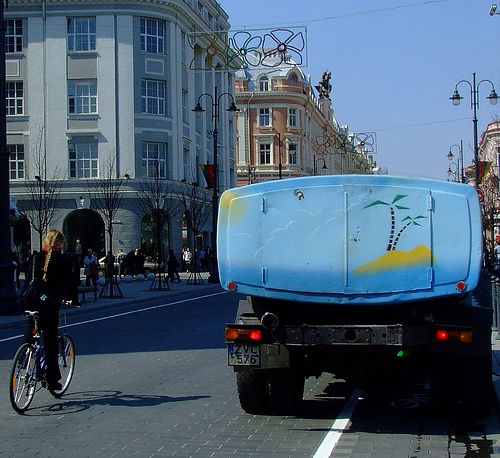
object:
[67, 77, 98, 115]
window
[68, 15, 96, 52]
window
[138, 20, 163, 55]
window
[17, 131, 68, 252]
trees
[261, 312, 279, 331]
exhaust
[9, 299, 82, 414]
bike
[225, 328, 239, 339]
rear lights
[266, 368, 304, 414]
wheels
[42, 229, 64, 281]
hair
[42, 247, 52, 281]
braid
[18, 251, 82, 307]
coat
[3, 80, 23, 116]
white window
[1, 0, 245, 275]
building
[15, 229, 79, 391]
girl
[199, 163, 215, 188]
banner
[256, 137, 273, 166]
window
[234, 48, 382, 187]
building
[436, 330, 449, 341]
tail light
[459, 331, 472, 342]
tail light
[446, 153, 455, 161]
ground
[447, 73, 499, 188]
cake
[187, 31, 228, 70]
flowers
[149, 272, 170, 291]
cage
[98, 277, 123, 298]
cage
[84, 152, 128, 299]
tree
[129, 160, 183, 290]
tree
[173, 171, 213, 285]
tree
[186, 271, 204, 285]
cage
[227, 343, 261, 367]
tag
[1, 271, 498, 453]
street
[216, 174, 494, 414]
truck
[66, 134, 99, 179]
window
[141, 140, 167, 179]
window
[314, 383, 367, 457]
line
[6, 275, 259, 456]
road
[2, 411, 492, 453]
road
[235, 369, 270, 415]
tires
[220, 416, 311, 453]
pavers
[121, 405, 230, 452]
pavers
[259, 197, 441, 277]
sign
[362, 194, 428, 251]
palm tree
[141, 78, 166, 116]
window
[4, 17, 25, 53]
window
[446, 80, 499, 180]
street light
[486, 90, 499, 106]
lamp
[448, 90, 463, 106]
lamp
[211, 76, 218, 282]
post